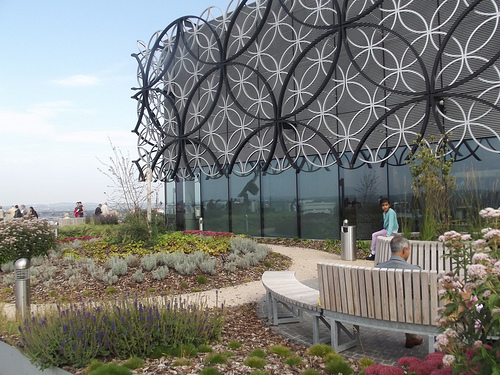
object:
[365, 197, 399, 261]
child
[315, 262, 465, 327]
bench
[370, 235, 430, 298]
man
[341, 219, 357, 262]
trash can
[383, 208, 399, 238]
shirt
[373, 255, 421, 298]
shirt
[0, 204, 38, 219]
people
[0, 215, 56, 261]
flowers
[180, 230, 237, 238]
flowers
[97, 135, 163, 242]
trees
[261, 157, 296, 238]
window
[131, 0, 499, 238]
building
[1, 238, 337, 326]
path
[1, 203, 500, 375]
garden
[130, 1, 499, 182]
design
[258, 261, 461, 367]
seat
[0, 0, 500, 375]
space